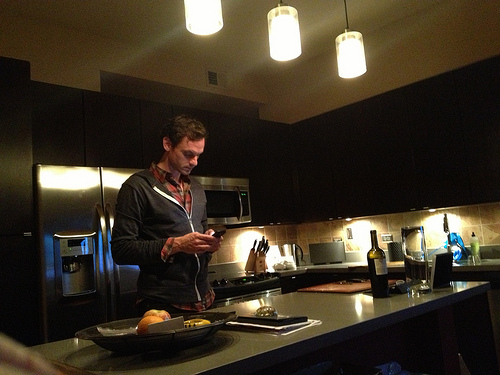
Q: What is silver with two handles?
A: Part of the refrigerator.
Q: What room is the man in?
A: The kitchen.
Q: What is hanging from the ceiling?
A: Lights.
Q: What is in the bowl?
A: Oranges.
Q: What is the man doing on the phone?
A: Texting.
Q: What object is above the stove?
A: A microwave.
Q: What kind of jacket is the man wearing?
A: A hoodie.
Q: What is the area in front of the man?
A: A kitchen island.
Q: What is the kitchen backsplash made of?
A: Tile.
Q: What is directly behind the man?
A: A Refrigerator.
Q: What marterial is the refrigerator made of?
A: Metal.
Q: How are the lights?
A: On.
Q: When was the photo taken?
A: Night.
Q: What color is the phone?
A: Black.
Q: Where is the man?
A: Kitchen.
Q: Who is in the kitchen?
A: A man.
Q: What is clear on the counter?
A: Vase.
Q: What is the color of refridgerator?
A: Stianless steel.